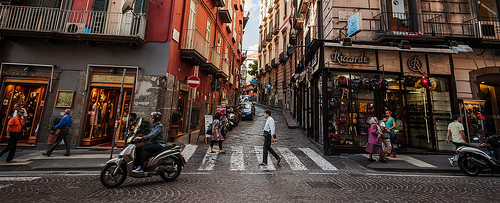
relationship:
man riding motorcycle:
[132, 111, 165, 173] [100, 138, 186, 185]